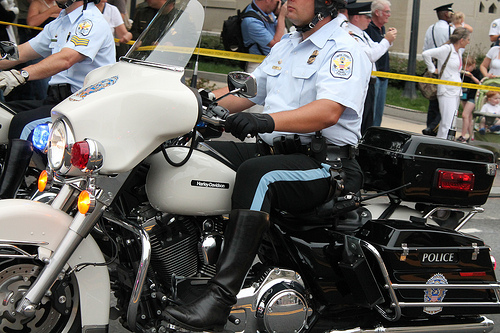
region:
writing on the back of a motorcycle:
[418, 249, 458, 263]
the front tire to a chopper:
[5, 210, 107, 330]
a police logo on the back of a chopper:
[418, 272, 453, 314]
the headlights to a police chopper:
[41, 120, 106, 180]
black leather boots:
[148, 211, 273, 330]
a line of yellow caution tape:
[135, 45, 497, 95]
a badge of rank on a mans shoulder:
[65, 30, 96, 47]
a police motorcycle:
[2, 65, 499, 331]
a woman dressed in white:
[417, 19, 474, 144]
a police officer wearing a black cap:
[426, 0, 460, 58]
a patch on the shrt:
[324, 50, 354, 89]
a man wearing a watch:
[18, 60, 38, 85]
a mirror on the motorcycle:
[224, 61, 261, 109]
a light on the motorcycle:
[432, 156, 477, 200]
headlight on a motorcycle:
[44, 118, 69, 168]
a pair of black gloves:
[223, 97, 286, 150]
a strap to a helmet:
[287, 10, 326, 42]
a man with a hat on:
[428, 3, 461, 26]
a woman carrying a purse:
[419, 37, 465, 107]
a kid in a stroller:
[470, 70, 497, 138]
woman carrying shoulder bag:
[414, 24, 473, 141]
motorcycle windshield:
[116, 0, 207, 71]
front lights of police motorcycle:
[31, 119, 106, 216]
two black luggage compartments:
[358, 123, 499, 329]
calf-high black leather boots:
[158, 205, 270, 331]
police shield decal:
[66, 72, 120, 103]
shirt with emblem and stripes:
[26, 1, 117, 93]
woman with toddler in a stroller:
[471, 33, 498, 138]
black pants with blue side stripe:
[229, 146, 353, 213]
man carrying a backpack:
[218, 0, 290, 75]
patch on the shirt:
[325, 53, 362, 85]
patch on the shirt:
[75, 20, 97, 41]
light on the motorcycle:
[53, 180, 97, 207]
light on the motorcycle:
[34, 177, 61, 193]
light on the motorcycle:
[64, 144, 90, 169]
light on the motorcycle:
[432, 165, 474, 190]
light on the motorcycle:
[50, 130, 80, 160]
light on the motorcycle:
[18, 129, 53, 149]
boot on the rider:
[178, 207, 261, 324]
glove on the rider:
[223, 114, 268, 147]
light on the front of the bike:
[27, 108, 103, 175]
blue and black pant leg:
[233, 145, 347, 216]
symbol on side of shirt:
[326, 44, 366, 85]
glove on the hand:
[223, 93, 294, 149]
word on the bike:
[405, 242, 465, 278]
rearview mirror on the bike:
[215, 64, 260, 111]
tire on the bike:
[0, 215, 105, 328]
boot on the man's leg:
[151, 207, 273, 331]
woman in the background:
[421, 23, 490, 84]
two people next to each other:
[79, 23, 394, 182]